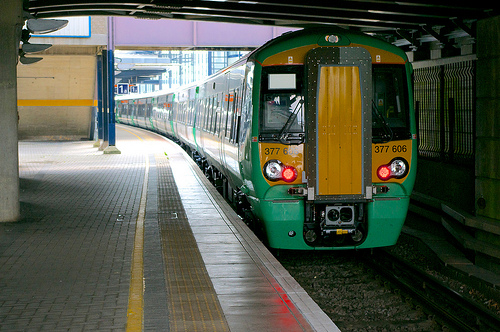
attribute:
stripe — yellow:
[114, 118, 167, 330]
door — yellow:
[315, 61, 367, 209]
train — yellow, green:
[107, 24, 420, 254]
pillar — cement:
[2, 8, 40, 218]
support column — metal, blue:
[92, 42, 120, 157]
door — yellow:
[312, 56, 372, 201]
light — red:
[263, 155, 293, 185]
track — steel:
[374, 229, 497, 329]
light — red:
[259, 146, 302, 188]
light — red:
[377, 147, 411, 198]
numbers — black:
[372, 140, 411, 161]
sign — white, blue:
[117, 79, 131, 98]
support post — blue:
[96, 43, 126, 153]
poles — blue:
[90, 51, 120, 159]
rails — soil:
[292, 243, 499, 327]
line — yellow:
[112, 118, 160, 330]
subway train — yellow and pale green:
[114, 27, 417, 254]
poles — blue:
[94, 46, 116, 147]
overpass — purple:
[108, 15, 302, 51]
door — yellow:
[317, 67, 365, 194]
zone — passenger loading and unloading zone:
[8, 122, 334, 331]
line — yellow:
[114, 124, 151, 330]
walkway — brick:
[0, 122, 145, 330]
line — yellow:
[16, 97, 96, 108]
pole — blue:
[107, 49, 116, 149]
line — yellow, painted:
[117, 124, 150, 329]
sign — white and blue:
[27, 15, 90, 40]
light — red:
[281, 167, 298, 184]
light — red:
[115, 31, 416, 250]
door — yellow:
[321, 68, 360, 198]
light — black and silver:
[263, 159, 281, 182]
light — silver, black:
[386, 151, 411, 179]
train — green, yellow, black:
[113, 15, 426, 265]